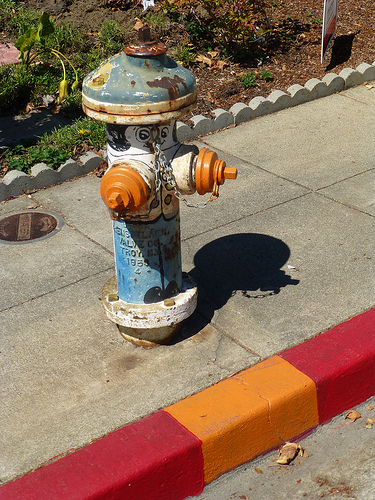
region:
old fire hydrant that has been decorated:
[80, 26, 236, 341]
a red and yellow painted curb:
[0, 308, 372, 498]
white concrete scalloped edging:
[3, 64, 373, 197]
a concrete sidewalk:
[0, 81, 373, 489]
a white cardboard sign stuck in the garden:
[317, 0, 340, 64]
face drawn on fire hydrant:
[107, 123, 170, 151]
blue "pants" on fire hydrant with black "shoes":
[114, 219, 186, 303]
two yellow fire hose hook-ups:
[98, 148, 244, 213]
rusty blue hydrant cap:
[79, 24, 203, 113]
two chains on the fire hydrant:
[123, 140, 218, 219]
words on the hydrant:
[99, 225, 177, 282]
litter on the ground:
[261, 415, 371, 451]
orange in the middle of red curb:
[179, 364, 311, 447]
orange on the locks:
[94, 172, 158, 212]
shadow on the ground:
[190, 236, 295, 300]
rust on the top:
[130, 24, 166, 59]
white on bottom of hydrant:
[107, 295, 195, 342]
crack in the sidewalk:
[209, 345, 242, 376]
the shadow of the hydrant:
[160, 234, 299, 345]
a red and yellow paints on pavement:
[0, 309, 373, 499]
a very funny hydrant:
[70, 22, 236, 346]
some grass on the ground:
[12, 135, 93, 160]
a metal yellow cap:
[196, 147, 237, 201]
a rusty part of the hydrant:
[148, 73, 191, 110]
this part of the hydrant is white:
[100, 290, 203, 346]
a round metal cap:
[0, 213, 57, 241]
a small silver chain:
[147, 144, 195, 208]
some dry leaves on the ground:
[70, 143, 109, 174]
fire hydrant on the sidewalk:
[78, 17, 240, 349]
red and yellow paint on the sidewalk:
[2, 292, 373, 498]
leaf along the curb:
[270, 437, 308, 468]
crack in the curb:
[234, 378, 276, 421]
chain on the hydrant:
[149, 142, 223, 219]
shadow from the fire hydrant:
[170, 224, 305, 350]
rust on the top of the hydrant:
[146, 75, 192, 103]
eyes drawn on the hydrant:
[134, 127, 172, 144]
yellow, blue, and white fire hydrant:
[68, 20, 239, 346]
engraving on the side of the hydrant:
[114, 225, 169, 273]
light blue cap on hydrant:
[84, 41, 201, 113]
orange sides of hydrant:
[96, 138, 225, 221]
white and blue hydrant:
[98, 120, 193, 341]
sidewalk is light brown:
[216, 199, 341, 364]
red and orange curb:
[39, 317, 362, 499]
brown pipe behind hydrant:
[10, 193, 53, 249]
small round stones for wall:
[1, 18, 314, 214]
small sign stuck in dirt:
[298, 3, 362, 60]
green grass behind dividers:
[6, 32, 68, 171]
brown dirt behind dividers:
[190, 10, 350, 101]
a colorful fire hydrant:
[79, 15, 239, 346]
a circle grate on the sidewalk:
[0, 209, 66, 245]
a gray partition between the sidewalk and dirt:
[0, 60, 374, 204]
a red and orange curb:
[0, 304, 374, 499]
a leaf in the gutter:
[275, 440, 310, 468]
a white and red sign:
[319, 0, 339, 63]